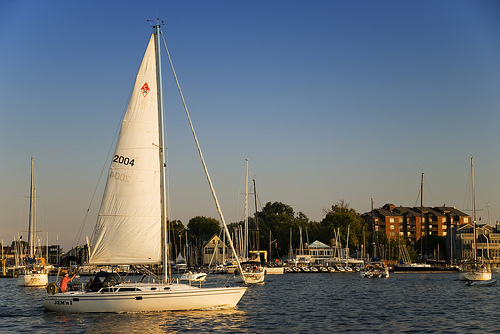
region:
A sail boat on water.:
[26, 26, 268, 321]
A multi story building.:
[360, 195, 471, 262]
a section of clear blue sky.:
[307, 17, 464, 111]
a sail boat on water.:
[24, 142, 52, 291]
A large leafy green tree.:
[240, 190, 302, 270]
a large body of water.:
[0, 270, 498, 332]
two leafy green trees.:
[165, 202, 230, 277]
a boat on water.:
[40, 269, 250, 326]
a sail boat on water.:
[449, 150, 498, 289]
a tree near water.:
[240, 192, 321, 269]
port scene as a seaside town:
[5, 4, 496, 330]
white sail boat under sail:
[41, 14, 248, 311]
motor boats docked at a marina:
[284, 262, 359, 273]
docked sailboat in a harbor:
[459, 154, 491, 282]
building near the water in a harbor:
[456, 219, 496, 270]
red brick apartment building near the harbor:
[362, 203, 471, 250]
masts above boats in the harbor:
[20, 150, 487, 205]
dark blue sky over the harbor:
[3, 3, 493, 76]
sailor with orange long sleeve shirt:
[60, 271, 79, 293]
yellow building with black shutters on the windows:
[196, 232, 233, 264]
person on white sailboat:
[55, 265, 77, 295]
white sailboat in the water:
[40, 43, 247, 311]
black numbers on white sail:
[111, 153, 138, 166]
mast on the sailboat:
[150, 19, 176, 284]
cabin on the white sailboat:
[97, 278, 187, 292]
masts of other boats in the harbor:
[15, 153, 493, 274]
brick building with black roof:
[368, 196, 475, 246]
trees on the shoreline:
[174, 193, 384, 255]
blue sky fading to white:
[7, 9, 497, 223]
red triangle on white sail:
[140, 80, 149, 90]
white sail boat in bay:
[37, 40, 248, 319]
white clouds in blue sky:
[221, 13, 273, 78]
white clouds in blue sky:
[289, 97, 336, 128]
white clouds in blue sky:
[197, 107, 249, 149]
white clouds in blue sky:
[28, 41, 81, 101]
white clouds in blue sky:
[45, 103, 79, 156]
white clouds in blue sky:
[388, 49, 465, 110]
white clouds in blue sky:
[334, 111, 384, 164]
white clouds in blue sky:
[239, 33, 299, 115]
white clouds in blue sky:
[293, 67, 367, 146]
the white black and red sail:
[84, 30, 162, 265]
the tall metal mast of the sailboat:
[24, 152, 38, 274]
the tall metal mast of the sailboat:
[242, 155, 248, 262]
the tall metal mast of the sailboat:
[470, 153, 481, 268]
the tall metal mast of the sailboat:
[368, 195, 378, 262]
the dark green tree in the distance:
[164, 215, 188, 260]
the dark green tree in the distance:
[186, 215, 220, 262]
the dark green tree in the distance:
[255, 198, 293, 265]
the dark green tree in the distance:
[311, 200, 360, 257]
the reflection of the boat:
[88, 308, 228, 332]